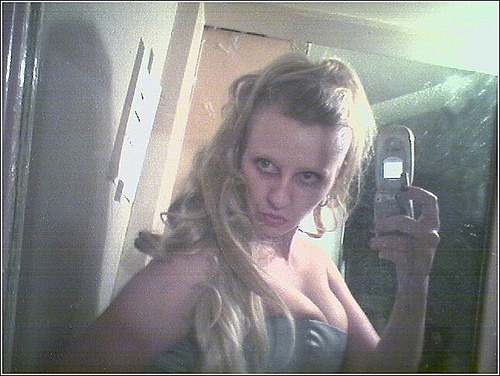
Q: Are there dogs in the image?
A: No, there are no dogs.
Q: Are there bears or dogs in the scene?
A: No, there are no dogs or bears.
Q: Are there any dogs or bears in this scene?
A: No, there are no dogs or bears.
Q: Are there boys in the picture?
A: No, there are no boys.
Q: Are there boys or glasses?
A: No, there are no boys or glasses.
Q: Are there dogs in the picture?
A: No, there are no dogs.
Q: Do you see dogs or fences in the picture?
A: No, there are no dogs or fences.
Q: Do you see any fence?
A: No, there are no fences.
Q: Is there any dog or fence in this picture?
A: No, there are no fences or dogs.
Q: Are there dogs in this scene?
A: No, there are no dogs.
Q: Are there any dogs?
A: No, there are no dogs.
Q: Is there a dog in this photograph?
A: No, there are no dogs.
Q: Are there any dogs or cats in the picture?
A: No, there are no dogs or cats.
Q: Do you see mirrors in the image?
A: Yes, there is a mirror.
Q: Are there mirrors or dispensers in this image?
A: Yes, there is a mirror.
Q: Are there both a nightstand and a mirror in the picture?
A: No, there is a mirror but no nightstands.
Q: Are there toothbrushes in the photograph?
A: No, there are no toothbrushes.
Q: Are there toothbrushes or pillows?
A: No, there are no toothbrushes or pillows.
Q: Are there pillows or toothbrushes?
A: No, there are no toothbrushes or pillows.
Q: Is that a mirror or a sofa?
A: That is a mirror.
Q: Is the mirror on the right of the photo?
A: Yes, the mirror is on the right of the image.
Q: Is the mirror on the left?
A: No, the mirror is on the right of the image.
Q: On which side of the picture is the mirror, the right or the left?
A: The mirror is on the right of the image.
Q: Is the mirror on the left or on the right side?
A: The mirror is on the right of the image.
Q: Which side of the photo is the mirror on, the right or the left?
A: The mirror is on the right of the image.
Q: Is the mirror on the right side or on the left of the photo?
A: The mirror is on the right of the image.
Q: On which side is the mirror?
A: The mirror is on the right of the image.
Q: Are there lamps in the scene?
A: No, there are no lamps.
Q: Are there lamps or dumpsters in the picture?
A: No, there are no lamps or dumpsters.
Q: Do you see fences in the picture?
A: No, there are no fences.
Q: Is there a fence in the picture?
A: No, there are no fences.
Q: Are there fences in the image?
A: No, there are no fences.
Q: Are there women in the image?
A: Yes, there is a woman.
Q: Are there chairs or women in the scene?
A: Yes, there is a woman.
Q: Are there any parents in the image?
A: No, there are no parents.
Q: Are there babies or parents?
A: No, there are no parents or babies.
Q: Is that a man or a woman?
A: That is a woman.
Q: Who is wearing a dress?
A: The woman is wearing a dress.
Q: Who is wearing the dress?
A: The woman is wearing a dress.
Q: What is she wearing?
A: The woman is wearing a dress.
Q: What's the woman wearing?
A: The woman is wearing a dress.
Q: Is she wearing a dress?
A: Yes, the woman is wearing a dress.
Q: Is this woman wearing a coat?
A: No, the woman is wearing a dress.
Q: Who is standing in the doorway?
A: The woman is standing in the doorway.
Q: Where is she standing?
A: The woman is standing in the doorway.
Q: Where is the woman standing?
A: The woman is standing in the doorway.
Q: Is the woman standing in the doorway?
A: Yes, the woman is standing in the doorway.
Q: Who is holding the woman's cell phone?
A: The woman is holding the cell phone.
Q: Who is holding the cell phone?
A: The woman is holding the cell phone.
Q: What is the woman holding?
A: The woman is holding the cell phone.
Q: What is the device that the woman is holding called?
A: The device is a cell phone.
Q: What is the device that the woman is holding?
A: The device is a cell phone.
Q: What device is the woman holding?
A: The woman is holding the cellphone.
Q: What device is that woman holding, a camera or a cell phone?
A: The woman is holding a cell phone.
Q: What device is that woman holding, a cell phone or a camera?
A: The woman is holding a cell phone.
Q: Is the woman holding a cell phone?
A: Yes, the woman is holding a cell phone.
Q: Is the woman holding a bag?
A: No, the woman is holding a cell phone.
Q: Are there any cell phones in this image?
A: Yes, there is a cell phone.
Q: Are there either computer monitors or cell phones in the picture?
A: Yes, there is a cell phone.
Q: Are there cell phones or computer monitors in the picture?
A: Yes, there is a cell phone.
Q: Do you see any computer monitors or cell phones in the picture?
A: Yes, there is a cell phone.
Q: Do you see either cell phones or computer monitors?
A: Yes, there is a cell phone.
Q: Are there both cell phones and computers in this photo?
A: No, there is a cell phone but no computers.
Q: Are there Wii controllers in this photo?
A: No, there are no Wii controllers.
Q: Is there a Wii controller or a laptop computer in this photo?
A: No, there are no Wii controllers or laptops.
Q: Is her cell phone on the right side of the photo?
A: Yes, the cell phone is on the right of the image.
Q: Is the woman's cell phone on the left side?
A: No, the mobile phone is on the right of the image.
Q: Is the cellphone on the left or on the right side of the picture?
A: The cellphone is on the right of the image.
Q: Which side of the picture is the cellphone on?
A: The cellphone is on the right of the image.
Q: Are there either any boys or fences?
A: No, there are no fences or boys.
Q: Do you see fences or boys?
A: No, there are no fences or boys.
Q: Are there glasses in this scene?
A: No, there are no glasses.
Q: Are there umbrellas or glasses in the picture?
A: No, there are no glasses or umbrellas.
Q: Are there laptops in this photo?
A: No, there are no laptops.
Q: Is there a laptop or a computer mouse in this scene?
A: No, there are no laptops or computer mice.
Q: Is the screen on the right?
A: Yes, the screen is on the right of the image.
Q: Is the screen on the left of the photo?
A: No, the screen is on the right of the image.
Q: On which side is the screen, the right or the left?
A: The screen is on the right of the image.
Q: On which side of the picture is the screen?
A: The screen is on the right of the image.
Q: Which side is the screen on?
A: The screen is on the right of the image.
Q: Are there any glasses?
A: No, there are no glasses.